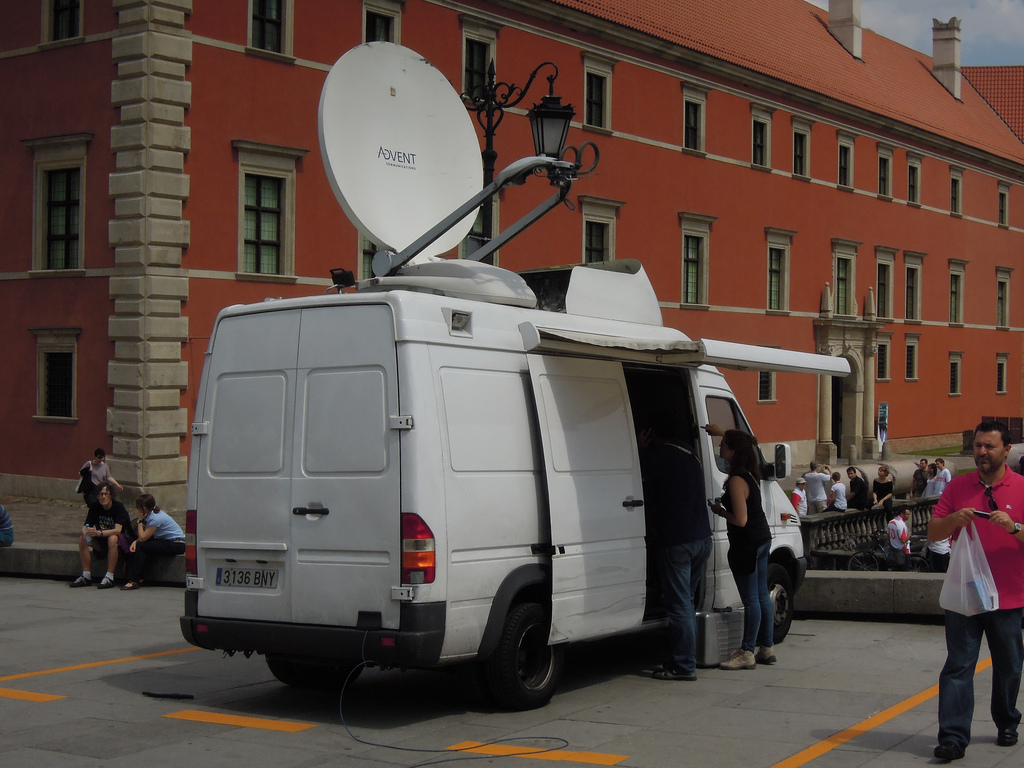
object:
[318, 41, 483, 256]
satellite dish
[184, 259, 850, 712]
van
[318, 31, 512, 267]
satellite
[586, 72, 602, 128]
window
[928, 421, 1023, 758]
man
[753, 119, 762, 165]
window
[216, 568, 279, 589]
licence plate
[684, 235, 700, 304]
window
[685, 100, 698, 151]
window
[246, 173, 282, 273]
window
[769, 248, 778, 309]
windows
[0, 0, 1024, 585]
building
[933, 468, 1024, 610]
pink shirt